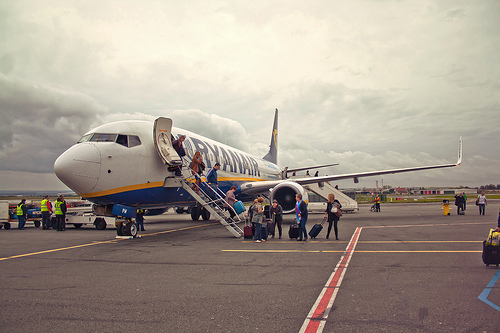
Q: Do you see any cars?
A: No, there are no cars.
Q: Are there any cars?
A: No, there are no cars.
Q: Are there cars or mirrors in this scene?
A: No, there are no cars or mirrors.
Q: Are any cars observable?
A: No, there are no cars.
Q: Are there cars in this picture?
A: No, there are no cars.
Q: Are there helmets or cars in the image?
A: No, there are no cars or helmets.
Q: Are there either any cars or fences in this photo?
A: No, there are no cars or fences.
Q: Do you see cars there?
A: No, there are no cars.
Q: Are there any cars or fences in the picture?
A: No, there are no cars or fences.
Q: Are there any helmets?
A: No, there are no helmets.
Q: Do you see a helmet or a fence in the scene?
A: No, there are no helmets or fences.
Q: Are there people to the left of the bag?
A: Yes, there is a person to the left of the bag.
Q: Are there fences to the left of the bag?
A: No, there is a person to the left of the bag.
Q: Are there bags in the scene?
A: Yes, there is a bag.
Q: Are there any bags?
A: Yes, there is a bag.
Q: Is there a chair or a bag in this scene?
A: Yes, there is a bag.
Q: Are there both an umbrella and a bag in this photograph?
A: No, there is a bag but no umbrellas.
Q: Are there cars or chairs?
A: No, there are no cars or chairs.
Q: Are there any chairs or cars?
A: No, there are no cars or chairs.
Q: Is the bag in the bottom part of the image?
A: Yes, the bag is in the bottom of the image.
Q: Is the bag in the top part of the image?
A: No, the bag is in the bottom of the image.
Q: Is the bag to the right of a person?
A: Yes, the bag is to the right of a person.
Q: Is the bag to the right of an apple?
A: No, the bag is to the right of a person.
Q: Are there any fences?
A: No, there are no fences.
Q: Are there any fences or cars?
A: No, there are no fences or cars.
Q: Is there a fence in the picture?
A: No, there are no fences.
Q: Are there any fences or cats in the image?
A: No, there are no fences or cats.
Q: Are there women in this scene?
A: Yes, there is a woman.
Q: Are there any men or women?
A: Yes, there is a woman.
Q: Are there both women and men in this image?
A: Yes, there are both a woman and a man.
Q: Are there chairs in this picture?
A: No, there are no chairs.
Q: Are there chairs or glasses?
A: No, there are no chairs or glasses.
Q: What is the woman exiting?
A: The woman is exiting the plane.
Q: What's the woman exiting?
A: The woman is exiting the plane.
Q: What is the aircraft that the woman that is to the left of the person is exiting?
A: The aircraft is an airplane.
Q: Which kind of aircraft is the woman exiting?
A: The woman is exiting the airplane.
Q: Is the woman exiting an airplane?
A: Yes, the woman is exiting an airplane.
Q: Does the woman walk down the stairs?
A: Yes, the woman walks down the stairs.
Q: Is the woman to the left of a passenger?
A: Yes, the woman is to the left of a passenger.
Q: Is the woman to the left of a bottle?
A: No, the woman is to the left of a passenger.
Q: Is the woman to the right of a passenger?
A: No, the woman is to the left of a passenger.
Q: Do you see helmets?
A: No, there are no helmets.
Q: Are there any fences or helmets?
A: No, there are no helmets or fences.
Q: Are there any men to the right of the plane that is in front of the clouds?
A: Yes, there is a man to the right of the plane.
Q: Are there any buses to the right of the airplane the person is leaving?
A: No, there is a man to the right of the airplane.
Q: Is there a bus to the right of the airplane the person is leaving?
A: No, there is a man to the right of the airplane.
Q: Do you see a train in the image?
A: No, there are no trains.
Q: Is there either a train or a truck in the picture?
A: No, there are no trains or trucks.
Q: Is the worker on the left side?
A: Yes, the worker is on the left of the image.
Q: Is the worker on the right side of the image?
A: No, the worker is on the left of the image.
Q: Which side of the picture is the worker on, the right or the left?
A: The worker is on the left of the image.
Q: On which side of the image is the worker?
A: The worker is on the left of the image.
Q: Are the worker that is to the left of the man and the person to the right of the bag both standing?
A: Yes, both the worker and the person are standing.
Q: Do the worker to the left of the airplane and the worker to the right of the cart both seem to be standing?
A: Yes, both the worker and the worker are standing.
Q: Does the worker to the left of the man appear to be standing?
A: Yes, the worker is standing.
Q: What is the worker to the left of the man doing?
A: The worker is standing.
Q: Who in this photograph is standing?
A: The worker is standing.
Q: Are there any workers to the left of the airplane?
A: Yes, there is a worker to the left of the airplane.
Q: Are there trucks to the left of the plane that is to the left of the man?
A: No, there is a worker to the left of the plane.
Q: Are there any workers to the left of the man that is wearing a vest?
A: Yes, there is a worker to the left of the man.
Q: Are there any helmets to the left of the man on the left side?
A: No, there is a worker to the left of the man.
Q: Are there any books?
A: No, there are no books.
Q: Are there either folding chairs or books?
A: No, there are no books or folding chairs.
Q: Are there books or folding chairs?
A: No, there are no books or folding chairs.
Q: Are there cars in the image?
A: No, there are no cars.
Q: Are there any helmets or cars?
A: No, there are no cars or helmets.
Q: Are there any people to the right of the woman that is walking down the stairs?
A: Yes, there is a person to the right of the woman.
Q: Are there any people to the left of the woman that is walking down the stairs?
A: No, the person is to the right of the woman.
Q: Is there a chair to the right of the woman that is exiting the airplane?
A: No, there is a person to the right of the woman.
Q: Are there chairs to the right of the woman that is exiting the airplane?
A: No, there is a person to the right of the woman.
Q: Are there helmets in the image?
A: No, there are no helmets.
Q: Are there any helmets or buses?
A: No, there are no helmets or buses.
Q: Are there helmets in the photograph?
A: No, there are no helmets.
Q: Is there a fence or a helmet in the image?
A: No, there are no helmets or fences.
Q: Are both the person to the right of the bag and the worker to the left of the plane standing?
A: Yes, both the person and the worker are standing.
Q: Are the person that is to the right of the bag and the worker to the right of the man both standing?
A: Yes, both the person and the worker are standing.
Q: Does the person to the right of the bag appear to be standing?
A: Yes, the person is standing.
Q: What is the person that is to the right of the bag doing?
A: The person is standing.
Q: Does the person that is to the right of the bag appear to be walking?
A: No, the person is standing.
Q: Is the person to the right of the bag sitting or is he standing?
A: The person is standing.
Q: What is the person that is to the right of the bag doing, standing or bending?
A: The person is standing.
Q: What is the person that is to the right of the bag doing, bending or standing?
A: The person is standing.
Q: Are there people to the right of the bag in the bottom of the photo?
A: Yes, there is a person to the right of the bag.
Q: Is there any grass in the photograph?
A: Yes, there is grass.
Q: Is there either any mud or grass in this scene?
A: Yes, there is grass.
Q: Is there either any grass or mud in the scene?
A: Yes, there is grass.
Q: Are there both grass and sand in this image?
A: No, there is grass but no sand.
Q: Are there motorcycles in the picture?
A: No, there are no motorcycles.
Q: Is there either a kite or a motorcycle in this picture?
A: No, there are no motorcycles or kites.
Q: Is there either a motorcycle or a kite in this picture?
A: No, there are no motorcycles or kites.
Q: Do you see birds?
A: No, there are no birds.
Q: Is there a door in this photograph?
A: Yes, there is a door.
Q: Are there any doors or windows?
A: Yes, there is a door.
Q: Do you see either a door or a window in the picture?
A: Yes, there is a door.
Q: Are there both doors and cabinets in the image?
A: No, there is a door but no cabinets.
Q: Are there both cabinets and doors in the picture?
A: No, there is a door but no cabinets.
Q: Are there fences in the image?
A: No, there are no fences.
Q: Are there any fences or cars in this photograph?
A: No, there are no fences or cars.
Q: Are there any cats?
A: No, there are no cats.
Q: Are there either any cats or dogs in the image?
A: No, there are no cats or dogs.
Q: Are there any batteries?
A: No, there are no batteries.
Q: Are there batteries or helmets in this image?
A: No, there are no batteries or helmets.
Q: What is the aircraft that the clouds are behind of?
A: The aircraft is an airplane.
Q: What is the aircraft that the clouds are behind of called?
A: The aircraft is an airplane.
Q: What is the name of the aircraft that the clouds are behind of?
A: The aircraft is an airplane.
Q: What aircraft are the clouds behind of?
A: The clouds are behind the plane.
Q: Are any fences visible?
A: No, there are no fences.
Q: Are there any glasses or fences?
A: No, there are no fences or glasses.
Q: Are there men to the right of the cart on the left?
A: Yes, there is a man to the right of the cart.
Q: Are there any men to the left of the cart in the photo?
A: No, the man is to the right of the cart.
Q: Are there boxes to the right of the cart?
A: No, there is a man to the right of the cart.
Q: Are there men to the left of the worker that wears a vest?
A: Yes, there is a man to the left of the worker.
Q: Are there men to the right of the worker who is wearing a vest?
A: No, the man is to the left of the worker.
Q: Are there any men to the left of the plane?
A: Yes, there is a man to the left of the plane.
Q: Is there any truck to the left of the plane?
A: No, there is a man to the left of the plane.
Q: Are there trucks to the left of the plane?
A: No, there is a man to the left of the plane.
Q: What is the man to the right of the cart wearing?
A: The man is wearing a vest.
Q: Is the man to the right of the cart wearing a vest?
A: Yes, the man is wearing a vest.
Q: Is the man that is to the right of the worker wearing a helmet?
A: No, the man is wearing a vest.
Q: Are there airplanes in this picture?
A: Yes, there is an airplane.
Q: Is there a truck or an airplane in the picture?
A: Yes, there is an airplane.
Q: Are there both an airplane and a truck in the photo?
A: No, there is an airplane but no trucks.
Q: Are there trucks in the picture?
A: No, there are no trucks.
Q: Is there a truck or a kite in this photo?
A: No, there are no trucks or kites.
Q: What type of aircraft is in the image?
A: The aircraft is an airplane.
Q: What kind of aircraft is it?
A: The aircraft is an airplane.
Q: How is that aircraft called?
A: This is an airplane.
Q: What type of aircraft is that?
A: This is an airplane.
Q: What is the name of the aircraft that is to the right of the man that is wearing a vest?
A: The aircraft is an airplane.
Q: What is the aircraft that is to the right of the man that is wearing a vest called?
A: The aircraft is an airplane.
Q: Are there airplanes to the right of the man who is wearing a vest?
A: Yes, there is an airplane to the right of the man.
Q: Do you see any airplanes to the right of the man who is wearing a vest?
A: Yes, there is an airplane to the right of the man.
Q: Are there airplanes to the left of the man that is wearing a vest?
A: No, the airplane is to the right of the man.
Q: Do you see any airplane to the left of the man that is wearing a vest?
A: No, the airplane is to the right of the man.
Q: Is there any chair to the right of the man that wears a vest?
A: No, there is an airplane to the right of the man.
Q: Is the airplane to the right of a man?
A: Yes, the airplane is to the right of a man.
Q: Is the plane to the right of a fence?
A: No, the plane is to the right of a man.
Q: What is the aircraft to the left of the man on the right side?
A: The aircraft is an airplane.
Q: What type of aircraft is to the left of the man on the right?
A: The aircraft is an airplane.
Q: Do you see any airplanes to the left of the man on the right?
A: Yes, there is an airplane to the left of the man.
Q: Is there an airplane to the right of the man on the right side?
A: No, the airplane is to the left of the man.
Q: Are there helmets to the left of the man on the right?
A: No, there is an airplane to the left of the man.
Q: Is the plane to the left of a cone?
A: No, the plane is to the left of a man.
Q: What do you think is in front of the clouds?
A: The plane is in front of the clouds.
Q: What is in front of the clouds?
A: The plane is in front of the clouds.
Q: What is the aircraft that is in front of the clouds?
A: The aircraft is an airplane.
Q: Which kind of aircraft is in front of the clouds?
A: The aircraft is an airplane.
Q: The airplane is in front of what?
A: The airplane is in front of the clouds.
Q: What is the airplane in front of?
A: The airplane is in front of the clouds.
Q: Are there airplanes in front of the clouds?
A: Yes, there is an airplane in front of the clouds.